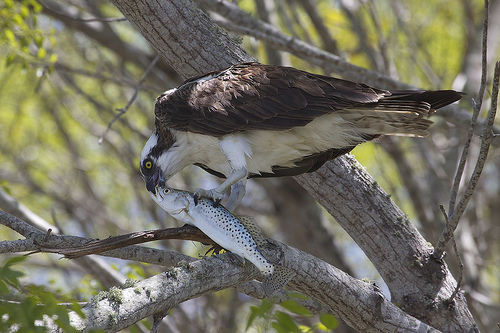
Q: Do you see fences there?
A: No, there are no fences.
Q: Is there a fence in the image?
A: No, there are no fences.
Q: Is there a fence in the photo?
A: No, there are no fences.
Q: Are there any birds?
A: Yes, there is a bird.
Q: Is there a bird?
A: Yes, there is a bird.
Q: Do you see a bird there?
A: Yes, there is a bird.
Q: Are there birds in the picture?
A: Yes, there is a bird.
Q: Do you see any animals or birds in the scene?
A: Yes, there is a bird.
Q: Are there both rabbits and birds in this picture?
A: No, there is a bird but no rabbits.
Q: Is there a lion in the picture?
A: No, there are no lions.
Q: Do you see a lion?
A: No, there are no lions.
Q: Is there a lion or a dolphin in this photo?
A: No, there are no lions or dolphins.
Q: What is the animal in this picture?
A: The animal is a bird.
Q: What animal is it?
A: The animal is a bird.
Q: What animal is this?
A: This is a bird.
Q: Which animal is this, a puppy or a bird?
A: This is a bird.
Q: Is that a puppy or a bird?
A: That is a bird.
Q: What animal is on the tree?
A: The animal is a bird.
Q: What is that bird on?
A: The bird is on the tree.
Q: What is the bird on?
A: The bird is on the tree.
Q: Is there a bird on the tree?
A: Yes, there is a bird on the tree.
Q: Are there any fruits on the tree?
A: No, there is a bird on the tree.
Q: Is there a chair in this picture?
A: No, there are no chairs.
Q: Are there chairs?
A: No, there are no chairs.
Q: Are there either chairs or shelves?
A: No, there are no chairs or shelves.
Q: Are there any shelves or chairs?
A: No, there are no chairs or shelves.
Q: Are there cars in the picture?
A: No, there are no cars.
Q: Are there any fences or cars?
A: No, there are no cars or fences.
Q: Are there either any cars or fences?
A: No, there are no cars or fences.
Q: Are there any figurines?
A: No, there are no figurines.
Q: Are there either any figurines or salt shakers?
A: No, there are no figurines or salt shakers.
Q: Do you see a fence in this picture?
A: No, there are no fences.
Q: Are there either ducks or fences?
A: No, there are no fences or ducks.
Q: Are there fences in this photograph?
A: No, there are no fences.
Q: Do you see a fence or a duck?
A: No, there are no fences or ducks.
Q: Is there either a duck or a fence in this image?
A: No, there are no fences or ducks.